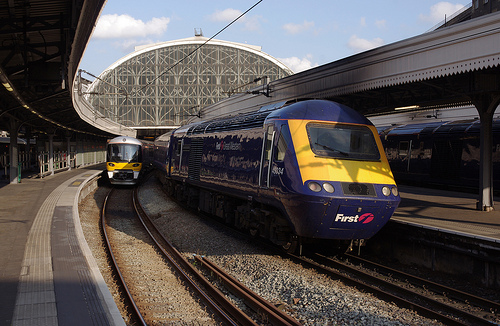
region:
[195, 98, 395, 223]
blue and yellow light rail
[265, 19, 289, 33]
white clouds in blue sky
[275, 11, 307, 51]
white clouds in blue sky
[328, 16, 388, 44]
white clouds in blue sky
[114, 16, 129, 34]
white clouds in blue sky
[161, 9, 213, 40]
white clouds in blue sky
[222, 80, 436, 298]
a train engine on track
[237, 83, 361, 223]
a bleu and yellow train engine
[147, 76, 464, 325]
a train on the tracks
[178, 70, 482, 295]
a passenger train on track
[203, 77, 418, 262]
track with atrian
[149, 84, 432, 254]
train track with train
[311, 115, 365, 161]
a window on train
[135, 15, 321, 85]
power line above train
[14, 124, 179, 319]
a sidewalk next to track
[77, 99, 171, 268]
a train on track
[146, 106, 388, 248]
the train is purple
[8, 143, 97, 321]
the platform is empty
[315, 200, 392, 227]
the word first on the train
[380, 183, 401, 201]
two head lights on the train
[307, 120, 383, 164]
a windshield on train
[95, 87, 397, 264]
two trains on the tracks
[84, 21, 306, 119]
a large round building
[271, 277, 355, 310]
gravel between the track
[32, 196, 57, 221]
some brown bricks on walk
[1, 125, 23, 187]
a round gray pillar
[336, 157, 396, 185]
a shadow on the train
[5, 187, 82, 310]
the platform is paved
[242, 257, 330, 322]
the gravel is gray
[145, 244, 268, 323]
the tracks are iron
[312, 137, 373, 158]
the wipers are black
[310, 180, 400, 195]
the headlights are off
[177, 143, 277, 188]
windows on the train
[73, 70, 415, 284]
trains on the track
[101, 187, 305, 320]
a set of tracks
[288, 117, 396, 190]
yellow front of train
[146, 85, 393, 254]
the train is blue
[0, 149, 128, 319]
platform next to train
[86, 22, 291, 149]
building in the background